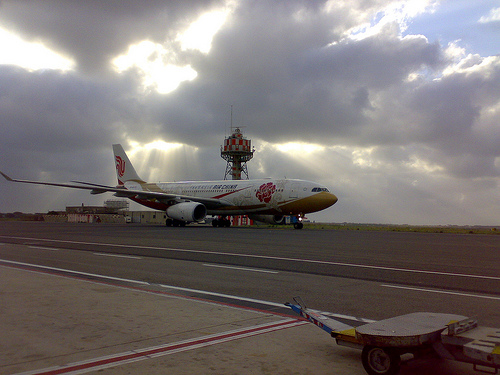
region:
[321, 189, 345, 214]
NOSE OF JET PLANE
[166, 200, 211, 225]
JET ENGINE FOR PLANE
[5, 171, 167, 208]
WING FOR JET PLANE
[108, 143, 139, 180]
TAIL SECTION FOR PLANE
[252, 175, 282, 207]
BRAND NAME FOR JET PLANE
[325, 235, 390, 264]
PART OF JET RUNWAY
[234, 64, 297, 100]
DARK STORMY CLOUDS OVERHEAD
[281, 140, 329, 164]
LIGHT TRYING TO SHINE THROUGH CLOUDS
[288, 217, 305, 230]
FRONT WHEEL OF JET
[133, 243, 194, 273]
WHITE RUNWAY STRIP MARKINGS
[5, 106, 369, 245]
the airplane is on the ground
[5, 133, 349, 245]
the plane is on the tarmac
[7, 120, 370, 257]
the plane is parked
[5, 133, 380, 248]
a plane in the airfield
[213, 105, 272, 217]
this is a tower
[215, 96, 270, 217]
the tower is orange and white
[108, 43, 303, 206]
the sunlight is shinging through the clouds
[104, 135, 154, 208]
there is a red logo on the tail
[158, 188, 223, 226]
the jet engine is white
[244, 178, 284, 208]
a red flower painted on the plane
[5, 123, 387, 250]
a plane on a runway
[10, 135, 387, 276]
a large passenger jet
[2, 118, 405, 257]
the plane is white and gold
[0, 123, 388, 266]
a passenger jet parked on the tarmac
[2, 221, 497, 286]
the grey tarmac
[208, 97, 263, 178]
this is a orange and white tower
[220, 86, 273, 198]
the tower has a checker pattern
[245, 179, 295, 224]
a flower decal on the side of the plane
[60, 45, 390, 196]
there is sunlight beaming through the clouds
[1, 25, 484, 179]
cloud's in the sky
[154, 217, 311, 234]
wheels on the plane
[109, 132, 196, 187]
ray's of sun in the sky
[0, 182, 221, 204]
wing of the plane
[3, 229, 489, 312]
runway for the plane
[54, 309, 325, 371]
stripe's on the runway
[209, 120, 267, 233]
tower on the runway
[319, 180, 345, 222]
nose of the plane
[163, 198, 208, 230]
engine on the plane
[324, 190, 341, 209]
NOSE OF JET PLANE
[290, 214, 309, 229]
WHEEL OF JET PLANE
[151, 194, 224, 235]
ENGINE OF JET PLANE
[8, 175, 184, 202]
WING OF JET PLANE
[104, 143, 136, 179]
TAIL SECTION OF PLANE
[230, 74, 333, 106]
DARK FORBODING CLOUDS IN SKY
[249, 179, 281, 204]
BRAND NAME OF JET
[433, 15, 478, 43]
PART OF LIGHT BLUE SKY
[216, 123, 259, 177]
PART OF RUNWAY CONTROL TOWER